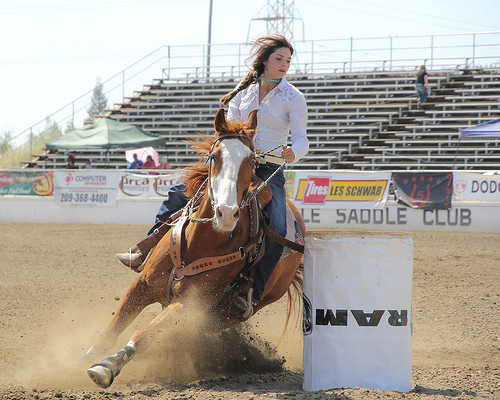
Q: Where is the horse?
A: In a stadium.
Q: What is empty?
A: Seats.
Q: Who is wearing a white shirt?
A: Woman's shirt.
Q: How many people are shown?
A: 1.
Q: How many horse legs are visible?
A: 2.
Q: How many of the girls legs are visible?
A: 2.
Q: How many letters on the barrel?
A: 3.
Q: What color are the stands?
A: Silver.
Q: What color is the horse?
A: Brown.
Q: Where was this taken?
A: Rodeo.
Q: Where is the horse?
A: In the dirt.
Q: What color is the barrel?
A: White.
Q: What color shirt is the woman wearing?
A: White.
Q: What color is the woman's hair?
A: Brown.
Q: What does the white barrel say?
A: RAM.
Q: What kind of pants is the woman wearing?
A: Jeans.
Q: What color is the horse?
A: Brown and white.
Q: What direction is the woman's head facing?
A: Right.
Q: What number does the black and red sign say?
A: 5.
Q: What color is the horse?
A: Brown and white.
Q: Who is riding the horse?
A: The girl.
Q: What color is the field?
A: Brown.